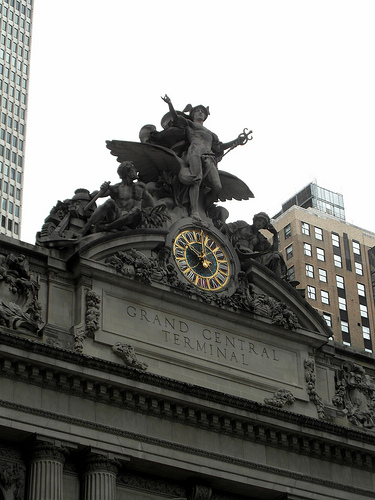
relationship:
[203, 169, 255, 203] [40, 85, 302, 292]
wing on statue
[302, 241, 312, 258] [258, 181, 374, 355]
window in building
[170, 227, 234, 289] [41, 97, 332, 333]
clock on tower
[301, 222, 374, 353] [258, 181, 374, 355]
windows on building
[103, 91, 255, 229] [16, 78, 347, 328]
statue on top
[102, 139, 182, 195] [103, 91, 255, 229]
wing on statue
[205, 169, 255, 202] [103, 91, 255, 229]
wing on statue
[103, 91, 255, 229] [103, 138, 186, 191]
statue has wing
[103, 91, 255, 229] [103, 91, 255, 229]
statue of statue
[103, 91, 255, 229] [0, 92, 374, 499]
statue on building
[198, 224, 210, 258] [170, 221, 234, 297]
hands on clock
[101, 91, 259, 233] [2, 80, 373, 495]
statue on building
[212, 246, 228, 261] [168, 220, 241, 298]
numeral on clock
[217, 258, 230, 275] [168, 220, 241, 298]
numeral on clock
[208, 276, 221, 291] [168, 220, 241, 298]
numeral on clock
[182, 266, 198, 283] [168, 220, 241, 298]
numeral on clock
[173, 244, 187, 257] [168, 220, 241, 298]
numeral on clock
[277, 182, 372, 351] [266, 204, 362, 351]
windows on building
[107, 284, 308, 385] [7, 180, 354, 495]
lettering on building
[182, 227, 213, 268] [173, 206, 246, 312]
hands on clock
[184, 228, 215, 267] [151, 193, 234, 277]
hands on clock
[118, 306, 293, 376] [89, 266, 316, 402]
letters on sign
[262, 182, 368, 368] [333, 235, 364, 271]
tall building with windows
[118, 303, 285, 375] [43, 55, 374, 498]
words on building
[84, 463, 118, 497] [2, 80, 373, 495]
column on building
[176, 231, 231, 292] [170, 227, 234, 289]
filigree on clock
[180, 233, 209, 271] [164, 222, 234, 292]
hands on clock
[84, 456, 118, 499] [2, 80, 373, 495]
column on building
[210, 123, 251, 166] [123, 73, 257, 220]
hands on statue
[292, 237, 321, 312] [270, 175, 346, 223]
bricks on tall building